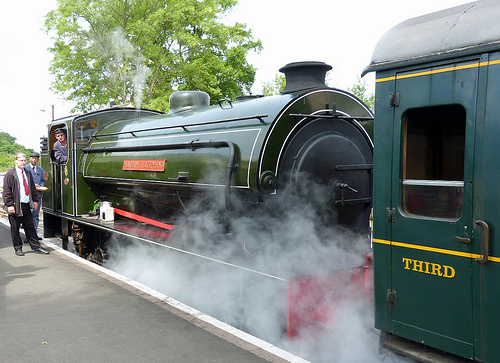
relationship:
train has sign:
[28, 2, 499, 361] [121, 157, 164, 169]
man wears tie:
[4, 149, 51, 257] [18, 168, 31, 193]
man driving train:
[51, 128, 72, 163] [28, 2, 499, 361]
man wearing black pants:
[4, 149, 51, 257] [8, 203, 42, 250]